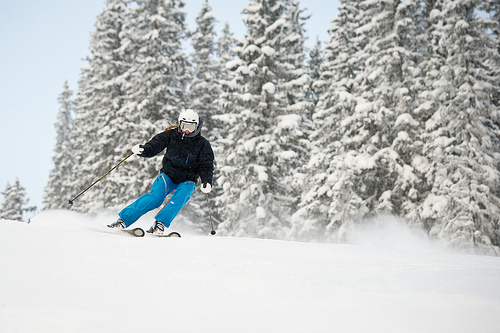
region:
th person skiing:
[74, 108, 223, 240]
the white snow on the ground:
[6, 223, 482, 331]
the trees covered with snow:
[8, 5, 498, 232]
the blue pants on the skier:
[112, 174, 194, 230]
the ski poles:
[76, 143, 218, 236]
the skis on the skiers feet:
[103, 218, 179, 237]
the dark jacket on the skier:
[138, 125, 218, 185]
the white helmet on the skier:
[178, 105, 203, 130]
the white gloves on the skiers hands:
[129, 143, 213, 193]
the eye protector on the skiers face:
[177, 118, 198, 133]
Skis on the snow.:
[96, 185, 246, 280]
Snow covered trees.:
[270, 24, 365, 74]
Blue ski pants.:
[134, 130, 218, 231]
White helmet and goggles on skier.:
[167, 109, 231, 219]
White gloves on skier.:
[127, 112, 184, 194]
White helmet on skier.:
[170, 96, 207, 199]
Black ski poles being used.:
[67, 109, 188, 213]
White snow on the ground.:
[35, 200, 110, 257]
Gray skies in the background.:
[25, 22, 99, 104]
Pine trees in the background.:
[232, 0, 387, 227]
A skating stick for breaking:
[200, 177, 222, 244]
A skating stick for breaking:
[61, 148, 141, 209]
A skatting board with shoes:
[104, 221, 179, 241]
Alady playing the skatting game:
[106, 106, 218, 253]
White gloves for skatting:
[130, 143, 151, 156]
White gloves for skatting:
[201, 176, 211, 198]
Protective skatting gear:
[142, 110, 204, 245]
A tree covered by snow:
[240, 5, 302, 232]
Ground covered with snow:
[30, 250, 385, 315]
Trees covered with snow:
[341, 5, 481, 271]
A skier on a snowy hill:
[76, 79, 242, 259]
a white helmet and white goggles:
[171, 108, 209, 142]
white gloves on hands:
[123, 143, 145, 162]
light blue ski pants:
[111, 172, 214, 240]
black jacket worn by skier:
[137, 121, 222, 192]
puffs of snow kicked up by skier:
[49, 183, 204, 241]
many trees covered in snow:
[70, 9, 499, 239]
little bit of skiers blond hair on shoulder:
[161, 118, 181, 135]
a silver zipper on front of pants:
[157, 170, 174, 205]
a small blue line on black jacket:
[184, 151, 199, 172]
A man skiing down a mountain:
[35, 61, 463, 313]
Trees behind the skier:
[44, 13, 499, 246]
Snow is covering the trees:
[252, 39, 491, 227]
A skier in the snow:
[82, 101, 232, 250]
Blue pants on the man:
[124, 176, 196, 222]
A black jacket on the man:
[149, 129, 216, 191]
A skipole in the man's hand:
[71, 140, 152, 207]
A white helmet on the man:
[178, 110, 198, 135]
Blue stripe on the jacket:
[185, 153, 192, 165]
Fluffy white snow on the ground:
[94, 256, 250, 298]